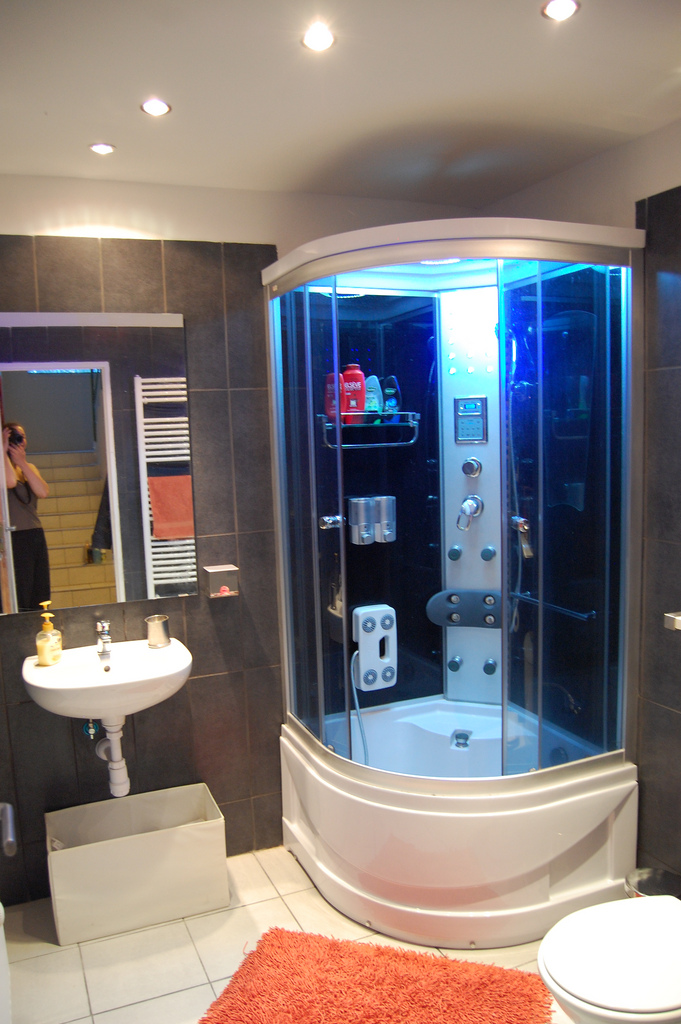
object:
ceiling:
[0, 0, 681, 178]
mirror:
[0, 364, 119, 612]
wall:
[110, 238, 225, 303]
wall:
[195, 726, 245, 761]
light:
[455, 298, 492, 334]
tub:
[41, 783, 228, 946]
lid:
[541, 891, 681, 1015]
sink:
[18, 618, 194, 798]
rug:
[185, 922, 552, 1024]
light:
[140, 95, 170, 122]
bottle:
[342, 362, 365, 424]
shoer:
[259, 211, 647, 952]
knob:
[459, 455, 481, 479]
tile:
[71, 927, 200, 1023]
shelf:
[315, 408, 427, 463]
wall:
[271, 314, 434, 706]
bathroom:
[0, 0, 681, 1024]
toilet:
[533, 884, 679, 1023]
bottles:
[324, 363, 349, 420]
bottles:
[363, 374, 384, 425]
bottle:
[381, 371, 403, 423]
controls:
[452, 395, 489, 446]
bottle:
[34, 597, 63, 670]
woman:
[2, 420, 55, 606]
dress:
[4, 465, 50, 610]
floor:
[5, 846, 532, 1015]